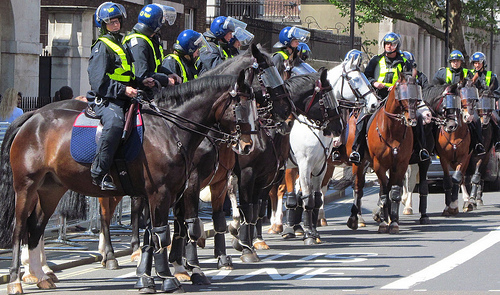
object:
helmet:
[94, 1, 129, 28]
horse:
[316, 71, 423, 235]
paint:
[109, 266, 375, 282]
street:
[1, 165, 500, 295]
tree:
[331, 0, 499, 71]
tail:
[1, 109, 35, 249]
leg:
[297, 164, 318, 246]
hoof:
[303, 237, 316, 245]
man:
[86, 0, 146, 191]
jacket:
[85, 31, 144, 102]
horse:
[1, 67, 260, 294]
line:
[378, 226, 500, 290]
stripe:
[120, 32, 162, 73]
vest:
[89, 37, 136, 83]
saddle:
[68, 96, 146, 191]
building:
[1, 0, 207, 132]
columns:
[417, 29, 424, 74]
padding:
[68, 105, 144, 165]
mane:
[147, 74, 240, 106]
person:
[0, 88, 24, 125]